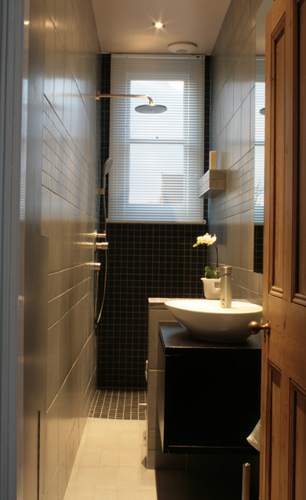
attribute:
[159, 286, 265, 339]
sink — white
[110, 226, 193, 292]
wall — black, back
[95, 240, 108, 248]
knob — silver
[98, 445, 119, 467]
tile — white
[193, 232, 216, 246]
bloom — white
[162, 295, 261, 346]
sink — white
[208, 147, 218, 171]
candle — white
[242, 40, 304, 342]
cabinet — black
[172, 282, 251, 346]
bowl — white, porcelain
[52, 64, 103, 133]
wall — black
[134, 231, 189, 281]
wall — black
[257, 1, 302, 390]
door — brown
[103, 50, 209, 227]
shades — white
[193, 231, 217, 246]
flower — white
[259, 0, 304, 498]
door — brown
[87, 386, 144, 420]
part — grey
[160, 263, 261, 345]
sink — white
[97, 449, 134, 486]
tile — white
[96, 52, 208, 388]
tile — black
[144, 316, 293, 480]
bathroom vanity — black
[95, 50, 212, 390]
wall — black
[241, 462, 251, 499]
handle — white, wooden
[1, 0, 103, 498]
tiled wall — black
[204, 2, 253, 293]
tiled wall — black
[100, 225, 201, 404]
tiled wall — black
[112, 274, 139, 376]
tile — black and grey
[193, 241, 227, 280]
leaf — green